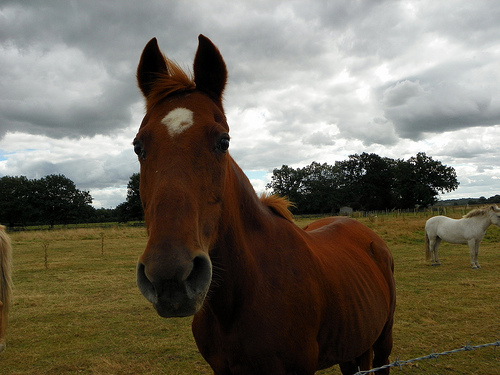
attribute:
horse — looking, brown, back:
[132, 34, 397, 374]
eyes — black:
[130, 133, 235, 159]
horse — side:
[423, 205, 500, 271]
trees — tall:
[0, 153, 461, 229]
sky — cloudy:
[1, 2, 499, 209]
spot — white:
[159, 106, 197, 139]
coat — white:
[426, 207, 499, 246]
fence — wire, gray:
[354, 338, 500, 374]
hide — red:
[310, 230, 387, 330]